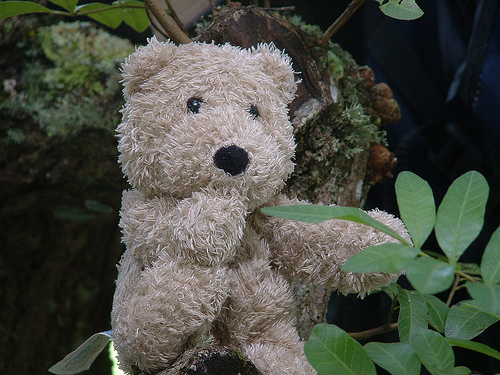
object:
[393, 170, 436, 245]
leaf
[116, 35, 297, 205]
face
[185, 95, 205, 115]
eye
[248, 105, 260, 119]
eye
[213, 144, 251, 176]
nose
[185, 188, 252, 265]
paw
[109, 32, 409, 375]
animal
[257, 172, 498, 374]
plant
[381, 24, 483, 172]
pattern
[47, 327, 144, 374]
tag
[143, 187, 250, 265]
arm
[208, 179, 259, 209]
mouth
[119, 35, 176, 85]
ear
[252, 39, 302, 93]
ear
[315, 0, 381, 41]
stick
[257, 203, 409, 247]
leaf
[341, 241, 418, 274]
leaf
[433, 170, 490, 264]
leaf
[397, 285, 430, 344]
leaf